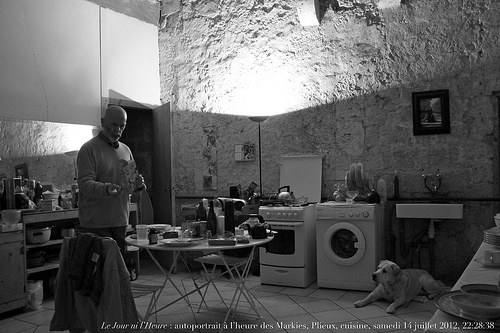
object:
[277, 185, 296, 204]
teapot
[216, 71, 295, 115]
light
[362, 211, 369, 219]
knob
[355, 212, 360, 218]
knob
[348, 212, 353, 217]
knob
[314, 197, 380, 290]
washing machine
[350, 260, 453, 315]
dog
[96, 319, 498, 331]
copyright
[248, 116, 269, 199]
pedestal lamp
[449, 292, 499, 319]
bowls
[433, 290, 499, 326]
plate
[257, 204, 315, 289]
stone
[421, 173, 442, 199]
faucets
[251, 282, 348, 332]
tile flooring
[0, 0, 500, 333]
room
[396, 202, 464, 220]
sink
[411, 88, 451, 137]
picture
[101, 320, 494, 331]
writing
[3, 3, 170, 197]
wall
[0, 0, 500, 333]
photo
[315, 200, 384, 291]
machines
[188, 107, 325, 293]
cooker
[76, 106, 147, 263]
man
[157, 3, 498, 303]
wall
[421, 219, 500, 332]
countertop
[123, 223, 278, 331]
table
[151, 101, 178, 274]
door